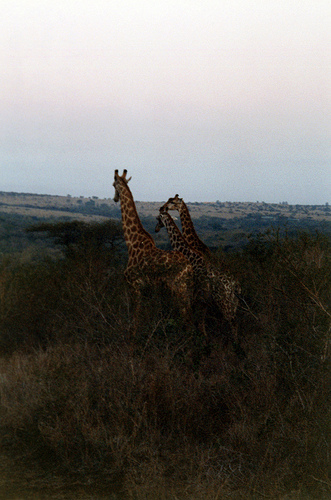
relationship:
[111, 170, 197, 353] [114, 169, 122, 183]
giraffe has horn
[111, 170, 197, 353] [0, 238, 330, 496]
giraffe in grass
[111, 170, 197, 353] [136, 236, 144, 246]
giraffe has spot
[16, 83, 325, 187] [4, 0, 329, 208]
cloud in sky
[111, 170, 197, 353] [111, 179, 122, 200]
giraffe has face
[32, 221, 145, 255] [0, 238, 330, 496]
tree in grass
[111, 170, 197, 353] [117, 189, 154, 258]
giraffe has neck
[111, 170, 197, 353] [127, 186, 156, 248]
giraffe has hair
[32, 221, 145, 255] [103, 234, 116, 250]
tree has branch